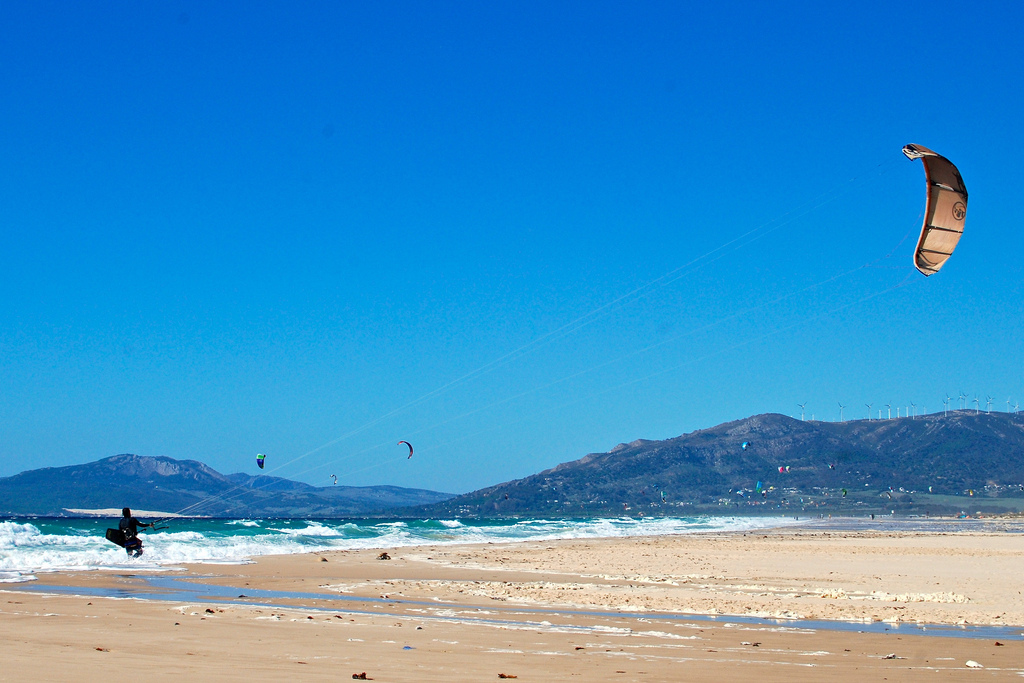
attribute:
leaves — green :
[252, 480, 320, 541]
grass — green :
[628, 355, 897, 503]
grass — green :
[617, 366, 847, 501]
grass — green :
[672, 364, 897, 531]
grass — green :
[676, 389, 875, 532]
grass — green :
[671, 346, 860, 519]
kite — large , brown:
[790, 72, 966, 369]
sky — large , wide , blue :
[84, 74, 851, 586]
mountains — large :
[432, 327, 834, 587]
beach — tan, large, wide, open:
[0, 500, 988, 676]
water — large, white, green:
[8, 510, 573, 543]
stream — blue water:
[624, 605, 970, 642]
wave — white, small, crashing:
[0, 517, 74, 572]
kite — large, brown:
[898, 134, 974, 273]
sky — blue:
[153, 104, 748, 351]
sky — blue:
[136, 55, 595, 256]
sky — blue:
[36, 35, 341, 316]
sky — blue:
[67, 135, 292, 235]